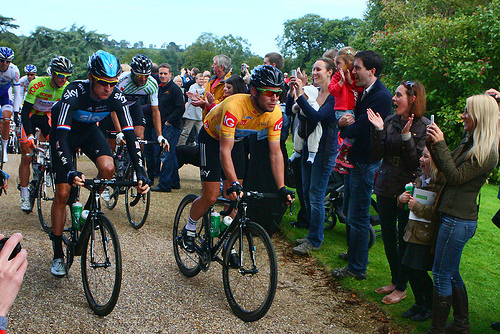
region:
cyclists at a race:
[4, 15, 481, 311]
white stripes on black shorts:
[196, 140, 209, 167]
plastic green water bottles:
[206, 206, 235, 231]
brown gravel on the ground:
[134, 266, 185, 328]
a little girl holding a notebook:
[406, 150, 438, 318]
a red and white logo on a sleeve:
[220, 107, 236, 130]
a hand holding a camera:
[0, 238, 30, 316]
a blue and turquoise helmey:
[84, 46, 131, 91]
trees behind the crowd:
[399, 9, 486, 79]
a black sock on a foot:
[51, 235, 63, 264]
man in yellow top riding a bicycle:
[172, 63, 297, 324]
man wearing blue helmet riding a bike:
[35, 49, 152, 320]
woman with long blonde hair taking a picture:
[425, 93, 498, 332]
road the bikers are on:
[2, 152, 397, 332]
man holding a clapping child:
[328, 46, 392, 281]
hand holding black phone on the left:
[0, 232, 28, 317]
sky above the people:
[0, 2, 366, 52]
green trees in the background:
[2, 3, 498, 100]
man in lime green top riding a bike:
[17, 56, 76, 213]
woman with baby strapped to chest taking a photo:
[284, 59, 336, 256]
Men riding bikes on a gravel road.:
[1, 30, 323, 310]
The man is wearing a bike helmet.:
[250, 62, 285, 87]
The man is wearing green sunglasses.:
[255, 83, 285, 98]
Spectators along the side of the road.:
[175, 12, 495, 329]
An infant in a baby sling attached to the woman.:
[290, 55, 335, 247]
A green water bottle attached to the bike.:
[202, 207, 222, 233]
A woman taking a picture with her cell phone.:
[422, 80, 498, 220]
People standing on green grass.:
[275, 221, 495, 326]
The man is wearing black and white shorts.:
[195, 127, 247, 187]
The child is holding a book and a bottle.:
[400, 140, 435, 320]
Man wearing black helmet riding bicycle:
[170, 63, 295, 320]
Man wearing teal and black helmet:
[45, 50, 145, 315]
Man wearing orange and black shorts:
[20, 56, 74, 233]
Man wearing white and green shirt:
[115, 54, 170, 229]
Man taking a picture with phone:
[425, 94, 498, 333]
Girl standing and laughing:
[400, 141, 445, 321]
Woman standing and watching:
[365, 79, 431, 305]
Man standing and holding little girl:
[328, 46, 392, 280]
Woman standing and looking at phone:
[285, 56, 336, 255]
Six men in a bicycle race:
[0, 46, 296, 322]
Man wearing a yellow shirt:
[199, 63, 286, 145]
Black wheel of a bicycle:
[222, 215, 279, 322]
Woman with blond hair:
[456, 90, 498, 168]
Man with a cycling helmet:
[83, 48, 122, 104]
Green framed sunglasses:
[250, 85, 286, 98]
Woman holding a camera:
[287, 56, 340, 117]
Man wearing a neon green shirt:
[25, 54, 72, 112]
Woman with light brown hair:
[391, 78, 428, 119]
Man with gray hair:
[209, 51, 232, 77]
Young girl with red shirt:
[330, 43, 357, 109]